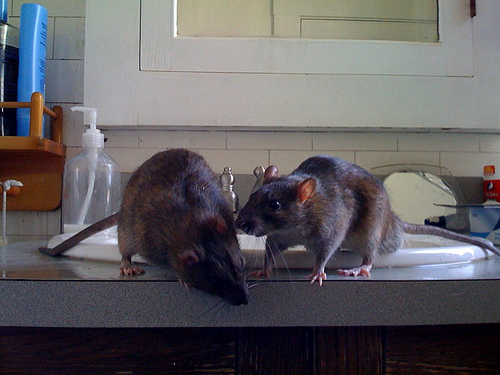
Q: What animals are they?
A: Mice.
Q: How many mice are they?
A: Two.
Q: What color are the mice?
A: Grey.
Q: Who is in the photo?
A: No one.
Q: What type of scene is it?
A: Indoor.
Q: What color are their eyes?
A: Black.